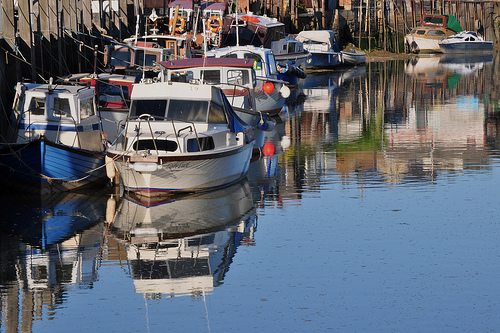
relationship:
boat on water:
[105, 80, 255, 207] [12, 55, 497, 327]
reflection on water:
[104, 154, 280, 299] [12, 55, 497, 327]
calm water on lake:
[0, 57, 499, 331] [0, 60, 498, 331]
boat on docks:
[105, 80, 258, 196] [0, 3, 367, 245]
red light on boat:
[256, 71, 298, 115] [207, 37, 295, 131]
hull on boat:
[7, 138, 107, 188] [5, 78, 110, 193]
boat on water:
[105, 80, 258, 196] [12, 55, 497, 327]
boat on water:
[2, 81, 105, 188] [12, 55, 497, 327]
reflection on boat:
[34, 198, 101, 253] [27, 122, 90, 187]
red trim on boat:
[77, 76, 133, 113] [72, 70, 137, 150]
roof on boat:
[155, 53, 257, 74] [97, 78, 259, 197]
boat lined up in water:
[205, 43, 294, 117] [12, 55, 497, 327]